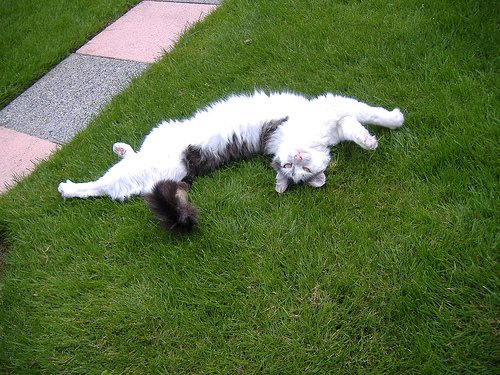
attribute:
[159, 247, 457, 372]
grass — green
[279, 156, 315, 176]
eyes — yellow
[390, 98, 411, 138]
claw — white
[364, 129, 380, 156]
claw — white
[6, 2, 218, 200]
tiles — pink, grey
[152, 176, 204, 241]
tail — black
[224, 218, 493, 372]
grass — green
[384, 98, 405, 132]
paw — white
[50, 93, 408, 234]
cat — white, black, fuzzy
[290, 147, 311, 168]
nose — pink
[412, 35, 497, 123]
grass is green — long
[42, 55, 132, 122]
sidewalk — different colored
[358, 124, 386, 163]
paw of cat — white